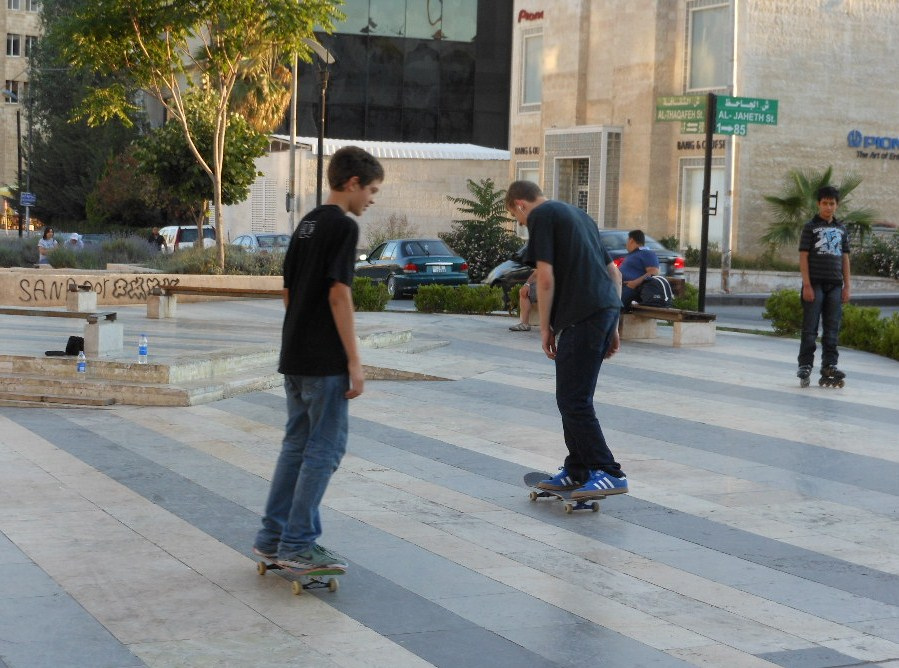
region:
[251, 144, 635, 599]
Two young boys on their skateboard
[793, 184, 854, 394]
Young boy on his rollerblades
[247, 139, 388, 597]
Young boy in blue jeans on skateboard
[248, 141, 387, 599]
Young boy in black shirt on his skateboard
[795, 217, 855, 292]
Black shirt with print on it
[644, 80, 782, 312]
Green and white street signs on post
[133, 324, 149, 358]
Plastic bottle water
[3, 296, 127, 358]
Empty concrete bench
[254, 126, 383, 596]
a boy riding a skateboard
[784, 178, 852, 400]
a boy wearing roller skates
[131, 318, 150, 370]
a plastic water bottle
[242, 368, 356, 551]
a boy wearing blue jeans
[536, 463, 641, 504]
a boy wearing blue and white shoes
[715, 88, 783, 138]
a green and white street sign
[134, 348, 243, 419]
a set of concrete steps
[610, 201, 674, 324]
a boy sitting on a bench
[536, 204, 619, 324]
a boy wearing a black shirt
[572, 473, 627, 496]
A blue shoe with white stripes.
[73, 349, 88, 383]
An empty bottle with blue sign.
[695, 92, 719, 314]
A thin and black pole.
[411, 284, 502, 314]
A small and green bush.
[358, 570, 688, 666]
Part of a black and gray stripes.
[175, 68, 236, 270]
A thin trunk of tree.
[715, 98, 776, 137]
A green signage with white writings.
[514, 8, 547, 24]
Red writings on cream wall.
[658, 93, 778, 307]
green signs on pole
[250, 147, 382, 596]
boy standing on skateboard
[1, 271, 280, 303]
graffiti on short wall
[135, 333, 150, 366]
water bottle with blue label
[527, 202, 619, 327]
short sleeve tee shirt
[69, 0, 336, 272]
green leaves on tree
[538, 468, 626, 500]
sneakers wirth white stripes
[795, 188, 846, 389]
boy on roller skates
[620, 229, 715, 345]
man seated on bench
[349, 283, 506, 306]
trimmed leaves of shrubs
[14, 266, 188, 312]
Black graffiti on a sandstone wall.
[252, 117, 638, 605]
Two boys riding skateboards on common area.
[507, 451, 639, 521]
Two blue adidas shoes on skateboard.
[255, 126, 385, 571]
Boy wearing black shirt and blue jeans.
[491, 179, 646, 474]
Guy wearing blakc shirt and jeans.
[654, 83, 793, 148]
Green street signs with white lettering.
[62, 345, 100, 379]
A discarded water bottle with blue packaging.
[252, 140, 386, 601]
A boy in tennis shoes riding skateboard.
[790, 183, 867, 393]
A boy in green top and jeans.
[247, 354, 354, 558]
boy wearing blue jeans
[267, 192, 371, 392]
boy wearing black shirt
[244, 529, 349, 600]
boy standing on skateboard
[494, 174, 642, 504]
young man on skateboard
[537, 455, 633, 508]
young man wearing tennis shoes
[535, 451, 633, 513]
man's shoes are blue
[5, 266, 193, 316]
grafitti on small wall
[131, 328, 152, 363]
water bottle on top of steps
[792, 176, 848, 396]
boy watch skateboarders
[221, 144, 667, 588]
Two guys skateboarding.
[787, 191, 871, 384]
A guy on rollerblades.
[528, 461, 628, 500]
A blue and white pair of shoes.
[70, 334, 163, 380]
Clear water bottles with blue labels.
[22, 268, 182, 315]
Graffiti on the side of a short wall.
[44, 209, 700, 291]
Vehicles parked along the side of the road.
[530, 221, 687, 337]
People sitting down on a bench.